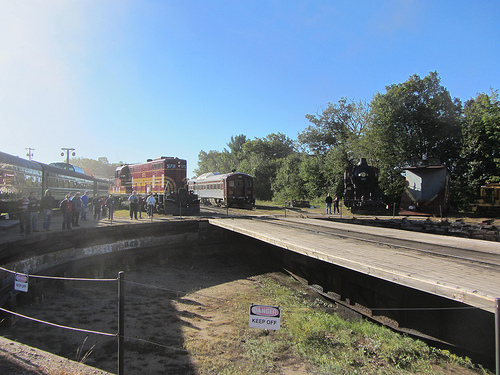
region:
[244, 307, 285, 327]
sign on the fence.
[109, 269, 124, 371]
fence post holding wire.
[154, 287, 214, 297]
wire attached to fence post.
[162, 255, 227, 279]
shade on the ground.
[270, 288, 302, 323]
grass on the ground.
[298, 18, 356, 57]
clear blue sky above trees.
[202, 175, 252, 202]
train on the tracks.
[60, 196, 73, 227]
person standing on the ledge.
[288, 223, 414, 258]
train tracks on bridge.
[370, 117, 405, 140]
leaves on the tree.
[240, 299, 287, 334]
danger keep off sign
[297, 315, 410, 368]
grass and dirt on the ground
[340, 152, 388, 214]
black train near people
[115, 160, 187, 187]
red and yellow train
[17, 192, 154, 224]
people standing together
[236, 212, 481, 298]
dirty railroad tracks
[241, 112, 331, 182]
green trees in the background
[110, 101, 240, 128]
clear blue sunny sky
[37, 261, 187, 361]
wire protective fencing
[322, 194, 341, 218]
two people standing near train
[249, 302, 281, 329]
danger sign on fence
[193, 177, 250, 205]
train driving on train tracks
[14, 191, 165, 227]
crowd of people to side of trains and train tracks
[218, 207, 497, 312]
grey train tracks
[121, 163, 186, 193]
red train car to the side of two other trains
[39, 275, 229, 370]
fence keeping people away from train tracks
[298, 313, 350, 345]
green grass to side of train tracks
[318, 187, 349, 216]
two people standing to right of train tracks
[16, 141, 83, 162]
telephone poles by trains and train tracks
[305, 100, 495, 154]
green trees and shrubbery by train tracks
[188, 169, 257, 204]
Train heading out in the distance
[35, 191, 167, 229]
People standing around beside trains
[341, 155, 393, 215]
Antique black train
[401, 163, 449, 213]
Small blue building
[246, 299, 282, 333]
Danger sign on wire fench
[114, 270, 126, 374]
Metal pole on the fence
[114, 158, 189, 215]
Large red and yellow train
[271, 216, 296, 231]
Part of the train tracks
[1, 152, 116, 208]
Long train and train cars behind people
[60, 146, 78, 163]
Railroad light above and behind the train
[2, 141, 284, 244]
Several trains at the station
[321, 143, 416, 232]
Engine sits inactive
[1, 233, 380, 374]
Area roped off for safety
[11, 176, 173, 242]
People on the platform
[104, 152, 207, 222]
Large red and yellow engine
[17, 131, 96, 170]
Telephone poles in the distance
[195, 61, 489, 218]
Trees adjacent to the station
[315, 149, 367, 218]
People looking at the old engine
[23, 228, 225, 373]
Dirt below the platform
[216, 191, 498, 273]
Tracks extend accross the bridge